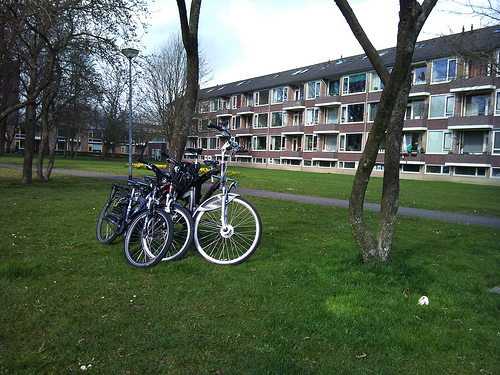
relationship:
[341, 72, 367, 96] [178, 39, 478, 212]
building window of a building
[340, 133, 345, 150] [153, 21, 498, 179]
window on building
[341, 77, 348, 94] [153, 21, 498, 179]
window on building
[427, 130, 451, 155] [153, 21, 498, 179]
window on building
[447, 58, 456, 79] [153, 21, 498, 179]
window on building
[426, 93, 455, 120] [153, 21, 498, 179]
window on building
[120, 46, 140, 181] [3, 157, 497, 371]
street lamp on grass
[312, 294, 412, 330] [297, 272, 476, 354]
patch on grass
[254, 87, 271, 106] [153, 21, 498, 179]
window on building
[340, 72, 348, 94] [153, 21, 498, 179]
building window on building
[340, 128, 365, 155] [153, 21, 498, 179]
window on building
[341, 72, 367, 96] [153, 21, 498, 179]
building window on building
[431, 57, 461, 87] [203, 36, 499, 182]
window on building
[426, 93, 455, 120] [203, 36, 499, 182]
window on building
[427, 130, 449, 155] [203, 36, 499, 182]
window on building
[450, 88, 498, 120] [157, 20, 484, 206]
window on building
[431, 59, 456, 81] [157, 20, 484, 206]
window on building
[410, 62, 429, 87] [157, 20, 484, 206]
window on building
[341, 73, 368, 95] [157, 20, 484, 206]
window on building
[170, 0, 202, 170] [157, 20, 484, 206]
trunk on building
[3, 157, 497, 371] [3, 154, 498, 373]
grass on lawn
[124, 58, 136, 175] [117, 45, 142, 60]
pole has light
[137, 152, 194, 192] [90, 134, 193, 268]
handle bars on bike